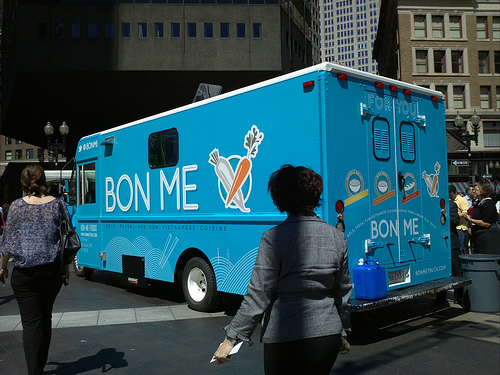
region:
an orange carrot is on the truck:
[226, 127, 263, 211]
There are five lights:
[321, 65, 446, 120]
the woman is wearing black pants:
[7, 162, 94, 344]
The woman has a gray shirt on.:
[220, 151, 362, 346]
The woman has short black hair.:
[252, 143, 347, 303]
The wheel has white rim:
[160, 236, 217, 313]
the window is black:
[127, 127, 198, 208]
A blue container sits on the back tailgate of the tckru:
[351, 246, 396, 311]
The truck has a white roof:
[95, 90, 317, 202]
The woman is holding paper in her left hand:
[205, 160, 342, 362]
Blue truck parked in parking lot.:
[48, 61, 495, 316]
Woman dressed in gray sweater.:
[2, 198, 68, 268]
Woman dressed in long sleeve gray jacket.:
[223, 217, 360, 347]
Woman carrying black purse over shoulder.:
[56, 204, 84, 268]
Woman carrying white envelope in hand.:
[201, 339, 253, 363]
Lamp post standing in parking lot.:
[449, 104, 494, 184]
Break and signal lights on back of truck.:
[422, 196, 448, 228]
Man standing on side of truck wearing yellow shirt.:
[449, 182, 473, 252]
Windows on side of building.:
[117, 13, 267, 52]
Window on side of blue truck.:
[138, 126, 190, 175]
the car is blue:
[75, 41, 457, 359]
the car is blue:
[76, 91, 287, 341]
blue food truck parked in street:
[19, 42, 437, 347]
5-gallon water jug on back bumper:
[304, 235, 466, 332]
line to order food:
[449, 158, 499, 244]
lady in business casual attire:
[166, 159, 368, 366]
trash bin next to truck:
[462, 237, 498, 327]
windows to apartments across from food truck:
[322, 12, 497, 77]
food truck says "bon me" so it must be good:
[92, 160, 284, 244]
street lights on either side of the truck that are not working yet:
[27, 91, 497, 207]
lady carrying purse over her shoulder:
[12, 158, 107, 365]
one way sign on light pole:
[438, 151, 490, 185]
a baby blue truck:
[66, 67, 453, 334]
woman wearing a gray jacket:
[234, 217, 356, 345]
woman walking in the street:
[7, 167, 101, 372]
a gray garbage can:
[461, 246, 498, 323]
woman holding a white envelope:
[198, 336, 257, 366]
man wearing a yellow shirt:
[452, 197, 476, 230]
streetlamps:
[34, 117, 79, 163]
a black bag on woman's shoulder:
[46, 195, 89, 271]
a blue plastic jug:
[348, 256, 398, 304]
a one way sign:
[448, 154, 478, 174]